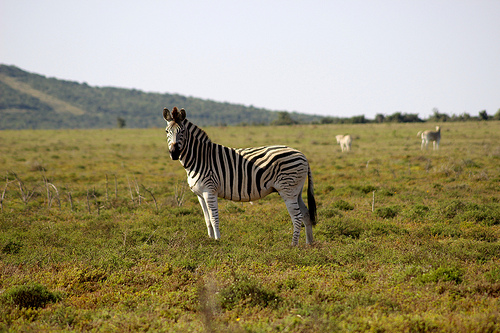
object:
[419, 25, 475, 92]
clouds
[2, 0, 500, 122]
sky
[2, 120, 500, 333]
foreground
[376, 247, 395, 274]
bad sentence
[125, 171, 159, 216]
branch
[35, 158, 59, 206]
branch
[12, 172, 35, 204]
branch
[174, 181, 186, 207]
branch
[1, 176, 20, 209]
branch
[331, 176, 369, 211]
bad sentence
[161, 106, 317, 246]
zebra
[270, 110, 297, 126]
tree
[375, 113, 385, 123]
tree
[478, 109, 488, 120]
tree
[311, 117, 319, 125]
tree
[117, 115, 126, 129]
tree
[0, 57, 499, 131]
background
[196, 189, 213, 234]
front leg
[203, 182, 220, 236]
front leg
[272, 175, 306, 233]
back leg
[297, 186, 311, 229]
back leg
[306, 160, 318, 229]
tail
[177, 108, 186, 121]
ear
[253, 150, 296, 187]
stripe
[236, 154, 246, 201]
stripe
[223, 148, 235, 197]
stripe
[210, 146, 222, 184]
stripe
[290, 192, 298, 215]
stripe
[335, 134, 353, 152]
animal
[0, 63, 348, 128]
hill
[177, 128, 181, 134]
eye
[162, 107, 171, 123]
ear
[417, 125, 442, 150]
llama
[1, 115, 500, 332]
field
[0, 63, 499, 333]
wilderness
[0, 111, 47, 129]
trees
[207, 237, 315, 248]
hooves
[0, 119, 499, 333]
grass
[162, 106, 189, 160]
head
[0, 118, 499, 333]
pasture